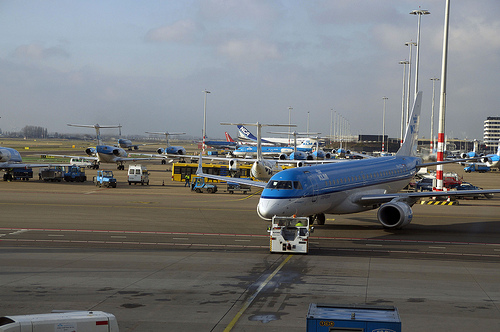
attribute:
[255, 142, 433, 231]
plane — blue, white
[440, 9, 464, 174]
light pole — striped, red, white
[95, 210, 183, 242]
runway — striped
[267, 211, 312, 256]
vehicle — white, maintaining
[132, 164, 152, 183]
van — white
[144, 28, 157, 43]
sky — gray, cloudy, blue, white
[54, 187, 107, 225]
lines — yellow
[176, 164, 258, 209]
bus — yellow, large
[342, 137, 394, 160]
building — terminal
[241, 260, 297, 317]
oil — black, wet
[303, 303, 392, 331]
container — blue, dolly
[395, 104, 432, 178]
tail — blue, white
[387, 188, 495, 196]
wings — big, silver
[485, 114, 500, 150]
building — white, black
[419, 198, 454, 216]
base — yellow, black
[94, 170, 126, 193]
car — blue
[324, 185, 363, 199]
stripe — black, red, white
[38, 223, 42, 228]
stripes — red, white